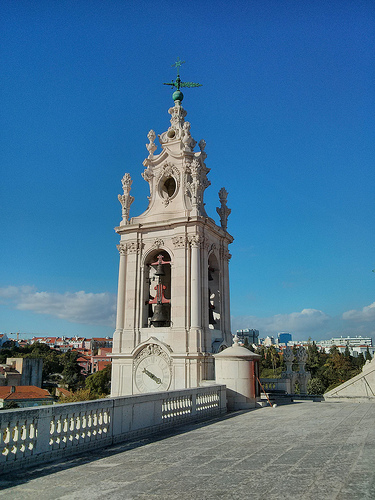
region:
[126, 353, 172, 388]
white clock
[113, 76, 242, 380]
tan clock tower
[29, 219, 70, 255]
white clouds in blue sky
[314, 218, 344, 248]
white clouds in blue sky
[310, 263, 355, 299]
white clouds in blue sky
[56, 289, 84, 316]
white clouds in blue sky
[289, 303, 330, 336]
white clouds in blue sky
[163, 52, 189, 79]
weather vane atop a steeple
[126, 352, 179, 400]
clock in the steeple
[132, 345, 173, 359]
ornamental decorations over clock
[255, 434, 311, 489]
gray bricks on walkway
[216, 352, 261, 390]
circular turret next to steeple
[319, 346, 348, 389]
green leaves on trees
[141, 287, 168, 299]
red bell in steeple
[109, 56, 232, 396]
clock and bell tower next to a building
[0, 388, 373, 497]
balcony area next to the clock tower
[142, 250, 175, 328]
bells on the inside of the tower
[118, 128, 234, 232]
decorative designs on the top of the tower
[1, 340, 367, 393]
dark green trees in the background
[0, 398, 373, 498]
brick pattern on the ground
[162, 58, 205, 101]
weather vane on the very top of the tower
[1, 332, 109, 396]
roof tops of the buildings seen from the balcony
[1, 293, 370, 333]
cumulous clouds in the sky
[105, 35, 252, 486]
a bell & clock tower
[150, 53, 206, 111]
a weather vane sits on top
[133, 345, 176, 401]
the clock reads 20 past 4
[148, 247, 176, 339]
a big bell & a small bell are in the tower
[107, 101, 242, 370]
the tower is very ornate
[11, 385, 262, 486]
a concrete balustrade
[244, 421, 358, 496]
the walkway is made of stone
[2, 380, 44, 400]
this roof is red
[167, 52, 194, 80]
a cross is at the very top of the tower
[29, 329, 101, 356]
many houses in the background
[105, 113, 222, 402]
TALL STONE CLOCK TOWER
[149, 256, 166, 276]
LARGE BELL IN TOWER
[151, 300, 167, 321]
LARGE BELL IN TOWER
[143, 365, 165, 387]
ARMS OF ROUND CLOCK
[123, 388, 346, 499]
CONCRETE SURFACE OF ROOF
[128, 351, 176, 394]
ROMAN NUMERALS ON CLOCK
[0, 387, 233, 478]
HOLES IN WALL ALONG ROOF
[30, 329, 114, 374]
RED ROOFS OF BUILDINGS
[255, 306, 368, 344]
WHITE CLOUDS IN SKY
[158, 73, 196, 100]
GREEN WEATHER VANE ON ROOF